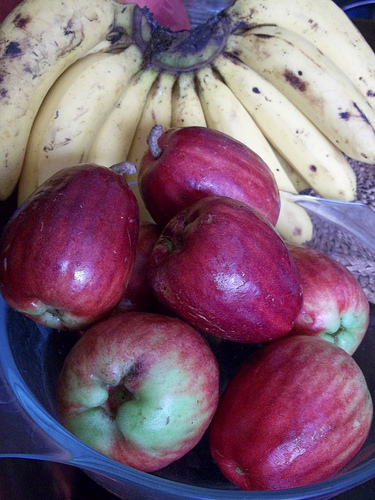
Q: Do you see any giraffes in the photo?
A: No, there are no giraffes.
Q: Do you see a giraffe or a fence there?
A: No, there are no giraffes or fences.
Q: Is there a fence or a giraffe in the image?
A: No, there are no giraffes or fences.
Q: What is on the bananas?
A: The spots are on the bananas.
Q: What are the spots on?
A: The spots are on the bananas.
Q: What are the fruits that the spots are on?
A: The fruits are bananas.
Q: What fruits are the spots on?
A: The spots are on the bananas.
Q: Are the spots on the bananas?
A: Yes, the spots are on the bananas.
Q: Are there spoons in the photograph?
A: No, there are no spoons.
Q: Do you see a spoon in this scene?
A: No, there are no spoons.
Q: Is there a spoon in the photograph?
A: No, there are no spoons.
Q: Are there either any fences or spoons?
A: No, there are no spoons or fences.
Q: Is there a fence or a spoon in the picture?
A: No, there are no spoons or fences.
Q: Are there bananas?
A: Yes, there are bananas.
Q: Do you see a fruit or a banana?
A: Yes, there are bananas.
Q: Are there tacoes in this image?
A: No, there are no tacoes.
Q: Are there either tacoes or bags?
A: No, there are no tacoes or bags.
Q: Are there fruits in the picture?
A: Yes, there is a fruit.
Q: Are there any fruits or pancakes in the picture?
A: Yes, there is a fruit.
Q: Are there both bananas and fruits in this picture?
A: Yes, there are both a fruit and a banana.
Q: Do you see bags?
A: No, there are no bags.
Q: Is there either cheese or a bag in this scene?
A: No, there are no bags or cheese.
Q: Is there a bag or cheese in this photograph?
A: No, there are no bags or cheese.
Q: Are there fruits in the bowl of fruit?
A: Yes, there is a fruit in the bowl.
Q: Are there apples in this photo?
A: Yes, there are apples.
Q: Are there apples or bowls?
A: Yes, there are apples.